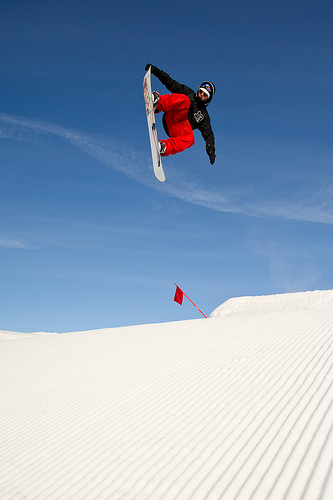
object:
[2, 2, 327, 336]
sky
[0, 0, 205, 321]
sky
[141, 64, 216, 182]
snowboarder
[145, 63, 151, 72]
hand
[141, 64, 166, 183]
board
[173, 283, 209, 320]
flag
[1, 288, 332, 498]
snow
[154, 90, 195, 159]
pants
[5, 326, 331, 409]
snow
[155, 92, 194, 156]
snow pants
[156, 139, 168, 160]
boot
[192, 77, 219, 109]
head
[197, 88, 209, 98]
sunglasses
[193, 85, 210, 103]
face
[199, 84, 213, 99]
hat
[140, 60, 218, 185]
man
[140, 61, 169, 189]
snowboard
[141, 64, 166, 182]
snowboard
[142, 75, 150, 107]
design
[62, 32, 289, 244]
air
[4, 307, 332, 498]
grooves